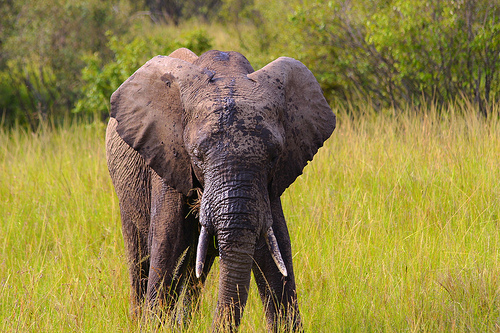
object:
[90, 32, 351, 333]
elephant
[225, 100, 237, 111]
mud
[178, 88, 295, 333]
face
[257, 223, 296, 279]
horn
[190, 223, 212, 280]
horn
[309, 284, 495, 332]
grass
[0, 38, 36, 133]
trees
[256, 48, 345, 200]
ear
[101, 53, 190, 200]
ear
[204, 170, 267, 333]
trunk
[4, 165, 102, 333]
grass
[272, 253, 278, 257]
black marks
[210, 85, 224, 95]
markings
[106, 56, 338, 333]
head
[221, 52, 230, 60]
markings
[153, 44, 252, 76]
back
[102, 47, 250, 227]
body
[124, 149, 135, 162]
wrinkles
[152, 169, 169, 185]
edges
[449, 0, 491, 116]
shrubs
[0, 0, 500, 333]
wild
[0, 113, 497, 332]
field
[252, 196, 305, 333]
leg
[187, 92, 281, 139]
forehead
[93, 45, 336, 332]
skin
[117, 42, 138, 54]
leaves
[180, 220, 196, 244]
shadow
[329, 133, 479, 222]
grass